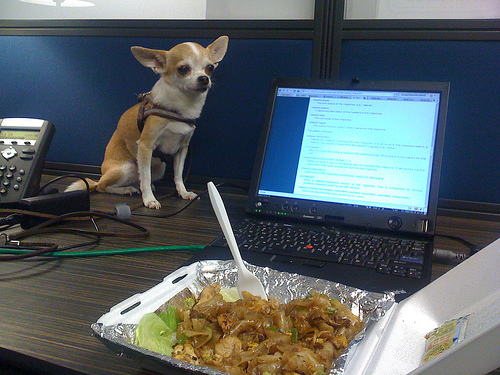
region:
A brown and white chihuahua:
[66, 34, 229, 211]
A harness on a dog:
[136, 88, 203, 165]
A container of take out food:
[92, 258, 497, 370]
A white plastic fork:
[205, 180, 267, 304]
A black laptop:
[185, 74, 452, 291]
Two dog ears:
[128, 34, 238, 70]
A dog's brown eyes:
[173, 59, 219, 74]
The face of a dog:
[129, 35, 231, 99]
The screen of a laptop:
[245, 75, 452, 237]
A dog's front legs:
[134, 129, 202, 213]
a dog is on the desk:
[68, 30, 230, 207]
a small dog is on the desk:
[72, 30, 233, 208]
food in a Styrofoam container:
[87, 178, 489, 372]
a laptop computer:
[200, 77, 455, 305]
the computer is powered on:
[196, 82, 432, 302]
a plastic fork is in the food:
[191, 182, 276, 312]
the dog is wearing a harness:
[91, 25, 229, 214]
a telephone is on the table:
[2, 107, 56, 227]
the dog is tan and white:
[83, 31, 214, 207]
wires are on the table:
[7, 180, 224, 276]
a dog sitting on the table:
[120, 36, 282, 230]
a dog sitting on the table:
[102, 20, 208, 218]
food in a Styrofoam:
[164, 226, 349, 371]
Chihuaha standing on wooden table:
[60, 33, 227, 212]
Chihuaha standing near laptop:
[58, 30, 233, 211]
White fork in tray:
[207, 182, 268, 303]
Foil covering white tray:
[86, 258, 396, 374]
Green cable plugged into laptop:
[0, 238, 207, 287]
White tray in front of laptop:
[87, 237, 498, 374]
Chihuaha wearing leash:
[62, 33, 232, 212]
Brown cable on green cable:
[0, 206, 147, 263]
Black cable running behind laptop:
[0, 174, 480, 255]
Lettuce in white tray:
[130, 308, 180, 350]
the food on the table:
[150, 275, 430, 372]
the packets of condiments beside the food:
[408, 310, 470, 362]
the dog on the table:
[106, 28, 223, 220]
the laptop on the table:
[246, 64, 453, 288]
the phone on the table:
[2, 105, 61, 220]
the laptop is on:
[231, 63, 447, 293]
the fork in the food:
[187, 175, 292, 316]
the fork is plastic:
[191, 177, 290, 306]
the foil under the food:
[206, 259, 474, 354]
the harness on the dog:
[120, 89, 204, 169]